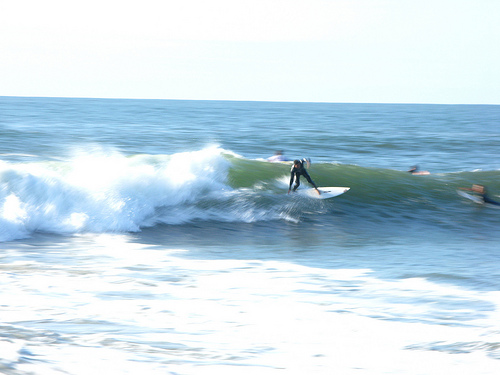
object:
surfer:
[276, 156, 315, 192]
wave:
[25, 129, 481, 242]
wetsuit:
[284, 167, 324, 189]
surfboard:
[280, 187, 351, 200]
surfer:
[451, 167, 490, 224]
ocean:
[52, 86, 462, 158]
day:
[5, 44, 382, 111]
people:
[264, 156, 477, 209]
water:
[81, 248, 401, 296]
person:
[283, 152, 323, 197]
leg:
[303, 175, 324, 195]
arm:
[286, 168, 293, 194]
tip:
[340, 180, 358, 204]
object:
[398, 159, 422, 182]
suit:
[294, 168, 317, 188]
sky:
[33, 6, 477, 100]